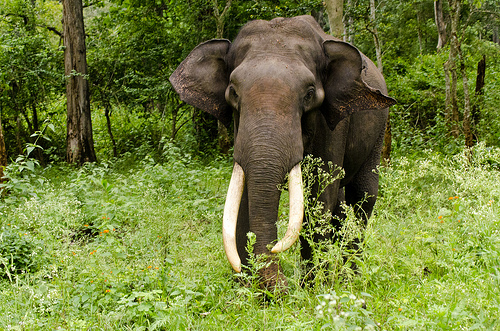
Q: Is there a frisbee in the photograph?
A: No, there are no frisbees.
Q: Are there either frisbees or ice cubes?
A: No, there are no frisbees or ice cubes.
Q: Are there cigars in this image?
A: No, there are no cigars.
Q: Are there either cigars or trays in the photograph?
A: No, there are no cigars or trays.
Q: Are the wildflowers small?
A: Yes, the wildflowers are small.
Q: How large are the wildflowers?
A: The wildflowers are small.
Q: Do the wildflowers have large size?
A: No, the wildflowers are small.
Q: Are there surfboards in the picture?
A: No, there are no surfboards.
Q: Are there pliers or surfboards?
A: No, there are no surfboards or pliers.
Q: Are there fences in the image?
A: No, there are no fences.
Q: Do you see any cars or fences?
A: No, there are no fences or cars.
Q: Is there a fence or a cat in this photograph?
A: No, there are no fences or cats.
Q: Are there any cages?
A: No, there are no cages.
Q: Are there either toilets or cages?
A: No, there are no cages or toilets.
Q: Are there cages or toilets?
A: No, there are no cages or toilets.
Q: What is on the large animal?
A: The trunk is on the elephant.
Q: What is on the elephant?
A: The trunk is on the elephant.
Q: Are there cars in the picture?
A: No, there are no cars.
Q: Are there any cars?
A: No, there are no cars.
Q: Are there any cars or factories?
A: No, there are no cars or factories.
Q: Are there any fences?
A: No, there are no fences.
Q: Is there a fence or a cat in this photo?
A: No, there are no fences or cats.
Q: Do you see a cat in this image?
A: No, there are no cats.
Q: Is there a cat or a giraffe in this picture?
A: No, there are no cats or giraffes.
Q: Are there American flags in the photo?
A: No, there are no American flags.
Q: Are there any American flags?
A: No, there are no American flags.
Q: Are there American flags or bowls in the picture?
A: No, there are no American flags or bowls.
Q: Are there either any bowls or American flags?
A: No, there are no American flags or bowls.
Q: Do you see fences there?
A: No, there are no fences.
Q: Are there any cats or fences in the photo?
A: No, there are no fences or cats.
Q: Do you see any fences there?
A: No, there are no fences.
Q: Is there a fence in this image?
A: No, there are no fences.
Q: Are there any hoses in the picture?
A: No, there are no hoses.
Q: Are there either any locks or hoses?
A: No, there are no hoses or locks.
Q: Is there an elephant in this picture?
A: Yes, there is an elephant.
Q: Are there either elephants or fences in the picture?
A: Yes, there is an elephant.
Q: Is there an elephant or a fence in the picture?
A: Yes, there is an elephant.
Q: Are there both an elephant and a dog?
A: No, there is an elephant but no dogs.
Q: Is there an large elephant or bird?
A: Yes, there is a large elephant.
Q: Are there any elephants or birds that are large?
A: Yes, the elephant is large.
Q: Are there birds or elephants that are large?
A: Yes, the elephant is large.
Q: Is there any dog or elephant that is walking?
A: Yes, the elephant is walking.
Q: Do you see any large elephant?
A: Yes, there is a large elephant.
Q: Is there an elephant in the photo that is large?
A: Yes, there is an elephant that is large.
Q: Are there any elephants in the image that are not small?
A: Yes, there is a large elephant.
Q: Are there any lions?
A: No, there are no lions.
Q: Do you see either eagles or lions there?
A: No, there are no lions or eagles.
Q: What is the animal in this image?
A: The animal is an elephant.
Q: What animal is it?
A: The animal is an elephant.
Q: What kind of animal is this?
A: This is an elephant.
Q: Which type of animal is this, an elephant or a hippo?
A: This is an elephant.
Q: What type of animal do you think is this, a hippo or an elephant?
A: This is an elephant.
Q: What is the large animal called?
A: The animal is an elephant.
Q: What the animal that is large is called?
A: The animal is an elephant.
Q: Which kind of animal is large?
A: The animal is an elephant.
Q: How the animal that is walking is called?
A: The animal is an elephant.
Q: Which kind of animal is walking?
A: The animal is an elephant.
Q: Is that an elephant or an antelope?
A: That is an elephant.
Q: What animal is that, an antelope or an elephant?
A: That is an elephant.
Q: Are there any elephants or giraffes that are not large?
A: No, there is an elephant but it is large.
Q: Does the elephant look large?
A: Yes, the elephant is large.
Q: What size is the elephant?
A: The elephant is large.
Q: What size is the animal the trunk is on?
A: The elephant is large.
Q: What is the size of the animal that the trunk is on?
A: The elephant is large.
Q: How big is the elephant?
A: The elephant is large.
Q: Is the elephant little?
A: No, the elephant is large.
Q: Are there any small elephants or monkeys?
A: No, there is an elephant but it is large.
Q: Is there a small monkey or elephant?
A: No, there is an elephant but it is large.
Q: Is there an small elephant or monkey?
A: No, there is an elephant but it is large.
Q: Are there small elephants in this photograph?
A: No, there is an elephant but it is large.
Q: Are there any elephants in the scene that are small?
A: No, there is an elephant but it is large.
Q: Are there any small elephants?
A: No, there is an elephant but it is large.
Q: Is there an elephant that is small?
A: No, there is an elephant but it is large.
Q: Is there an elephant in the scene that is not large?
A: No, there is an elephant but it is large.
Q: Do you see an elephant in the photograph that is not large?
A: No, there is an elephant but it is large.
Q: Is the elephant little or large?
A: The elephant is large.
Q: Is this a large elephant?
A: Yes, this is a large elephant.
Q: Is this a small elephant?
A: No, this is a large elephant.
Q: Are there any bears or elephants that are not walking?
A: No, there is an elephant but it is walking.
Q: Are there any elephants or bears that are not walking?
A: No, there is an elephant but it is walking.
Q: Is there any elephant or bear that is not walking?
A: No, there is an elephant but it is walking.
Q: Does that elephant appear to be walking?
A: Yes, the elephant is walking.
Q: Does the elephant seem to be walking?
A: Yes, the elephant is walking.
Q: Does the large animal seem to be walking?
A: Yes, the elephant is walking.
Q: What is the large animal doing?
A: The elephant is walking.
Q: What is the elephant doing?
A: The elephant is walking.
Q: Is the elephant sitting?
A: No, the elephant is walking.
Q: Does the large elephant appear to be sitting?
A: No, the elephant is walking.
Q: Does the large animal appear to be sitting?
A: No, the elephant is walking.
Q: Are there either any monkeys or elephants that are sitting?
A: No, there is an elephant but it is walking.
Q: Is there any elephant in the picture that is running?
A: No, there is an elephant but it is walking.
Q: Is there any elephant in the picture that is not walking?
A: No, there is an elephant but it is walking.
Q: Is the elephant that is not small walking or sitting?
A: The elephant is walking.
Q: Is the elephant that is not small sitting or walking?
A: The elephant is walking.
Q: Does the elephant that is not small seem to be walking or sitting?
A: The elephant is walking.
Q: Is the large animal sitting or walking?
A: The elephant is walking.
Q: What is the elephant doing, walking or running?
A: The elephant is walking.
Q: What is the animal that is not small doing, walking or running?
A: The elephant is walking.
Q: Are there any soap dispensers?
A: No, there are no soap dispensers.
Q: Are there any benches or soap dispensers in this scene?
A: No, there are no soap dispensers or benches.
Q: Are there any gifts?
A: No, there are no gifts.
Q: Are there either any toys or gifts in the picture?
A: No, there are no gifts or toys.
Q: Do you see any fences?
A: No, there are no fences.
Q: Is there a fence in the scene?
A: No, there are no fences.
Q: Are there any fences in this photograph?
A: No, there are no fences.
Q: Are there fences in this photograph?
A: No, there are no fences.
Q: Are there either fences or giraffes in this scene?
A: No, there are no fences or giraffes.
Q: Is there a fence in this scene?
A: No, there are no fences.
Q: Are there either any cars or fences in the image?
A: No, there are no fences or cars.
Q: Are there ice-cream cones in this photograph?
A: No, there are no ice-cream cones.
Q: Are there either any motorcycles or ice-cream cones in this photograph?
A: No, there are no ice-cream cones or motorcycles.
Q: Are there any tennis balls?
A: No, there are no tennis balls.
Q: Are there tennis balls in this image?
A: No, there are no tennis balls.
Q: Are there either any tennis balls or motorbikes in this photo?
A: No, there are no tennis balls or motorbikes.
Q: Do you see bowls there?
A: No, there are no bowls.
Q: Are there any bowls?
A: No, there are no bowls.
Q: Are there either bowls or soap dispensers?
A: No, there are no bowls or soap dispensers.